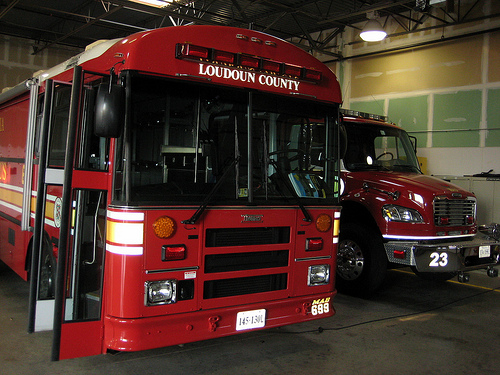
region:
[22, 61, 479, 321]
Two trucks are parked in the shed.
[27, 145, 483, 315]
Trucks are red color.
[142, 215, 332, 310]
Six lights are in front of the truck.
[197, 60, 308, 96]
Letters are white color.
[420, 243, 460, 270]
23 is written in the truck.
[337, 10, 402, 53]
Light is attached to the iron rods in ceiling.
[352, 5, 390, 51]
Lights are on.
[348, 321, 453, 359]
Floor is grey color.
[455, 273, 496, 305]
Yellow lines are in floor.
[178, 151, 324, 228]
Windshield wipers are black color.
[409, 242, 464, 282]
23 DISPLAYED ON THE BUMPER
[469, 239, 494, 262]
LICENSE PLATE ON THE BUMPER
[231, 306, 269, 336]
LICENSE PLATE ON THE BUMPER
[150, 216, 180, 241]
ORANGE SIGNAL LIGHT IN THE FRONT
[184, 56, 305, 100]
THE WORDS LOUDOUN COUNTY ARE DISPLAYED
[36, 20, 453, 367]
THE TRUCKS ARE IN A GARAGE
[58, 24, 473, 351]
BOTH TRUCKS ARE USED FOR EMERGENCIES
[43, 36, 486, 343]
BOTH TRUCKS ARE CONSIDERED FIRE APPARATUS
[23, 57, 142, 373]
THE TRUCK DOORS ARE OPEN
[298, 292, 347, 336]
THIS IS TRUCK 699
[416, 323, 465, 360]
part of a road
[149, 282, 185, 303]
part of a headlight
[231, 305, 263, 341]
part of a numberplate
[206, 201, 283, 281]
front of a bus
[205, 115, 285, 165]
part of a window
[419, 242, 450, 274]
part of a number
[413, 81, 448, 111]
part of a wall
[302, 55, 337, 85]
part of an upper edge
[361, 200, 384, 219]
part of a guard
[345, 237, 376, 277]
part of a wheel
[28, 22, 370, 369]
Loudoun County public bus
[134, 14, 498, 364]
red truck next to bus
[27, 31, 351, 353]
bus with opened doors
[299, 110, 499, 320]
truck with number 23 on bumper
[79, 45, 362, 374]
bus with number 699 on bumper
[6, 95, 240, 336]
orange and white stripes on bus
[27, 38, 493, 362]
vehicles at fire station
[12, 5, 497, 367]
truck and bus parked in garage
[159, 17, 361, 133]
emergency lights on bus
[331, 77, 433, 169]
emergency lights on fire truck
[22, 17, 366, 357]
large red passenger bus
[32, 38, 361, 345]
Red bus with the letter L on it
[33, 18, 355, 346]
Red bus with the letter O on it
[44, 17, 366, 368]
Red bus with the letter U on it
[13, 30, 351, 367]
Red bus with the letter D on it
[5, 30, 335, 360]
Red bus with the numbers 699 on it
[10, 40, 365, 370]
Red bus with the letter T on it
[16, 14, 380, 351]
Red bus with the letter Y on it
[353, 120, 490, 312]
Red truck with the number 23 on it